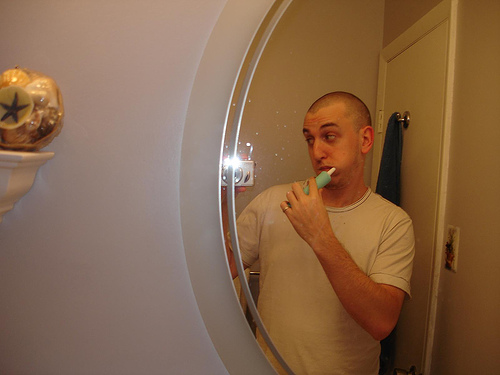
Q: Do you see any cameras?
A: Yes, there is a camera.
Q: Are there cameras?
A: Yes, there is a camera.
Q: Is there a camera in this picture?
A: Yes, there is a camera.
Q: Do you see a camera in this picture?
A: Yes, there is a camera.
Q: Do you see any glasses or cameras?
A: Yes, there is a camera.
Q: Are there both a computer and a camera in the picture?
A: No, there is a camera but no computers.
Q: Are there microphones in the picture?
A: No, there are no microphones.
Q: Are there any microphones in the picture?
A: No, there are no microphones.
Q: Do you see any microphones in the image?
A: No, there are no microphones.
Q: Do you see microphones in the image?
A: No, there are no microphones.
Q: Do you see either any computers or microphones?
A: No, there are no microphones or computers.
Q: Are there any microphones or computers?
A: No, there are no microphones or computers.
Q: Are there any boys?
A: No, there are no boys.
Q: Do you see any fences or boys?
A: No, there are no boys or fences.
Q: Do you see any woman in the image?
A: No, there are no women.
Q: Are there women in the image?
A: No, there are no women.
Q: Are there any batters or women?
A: No, there are no women or batters.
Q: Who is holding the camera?
A: The man is holding the camera.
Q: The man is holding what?
A: The man is holding the camera.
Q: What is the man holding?
A: The man is holding the camera.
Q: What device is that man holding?
A: The man is holding the camera.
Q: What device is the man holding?
A: The man is holding the camera.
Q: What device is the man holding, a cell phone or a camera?
A: The man is holding a camera.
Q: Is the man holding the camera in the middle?
A: Yes, the man is holding the camera.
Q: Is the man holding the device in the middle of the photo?
A: Yes, the man is holding the camera.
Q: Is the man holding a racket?
A: No, the man is holding the camera.